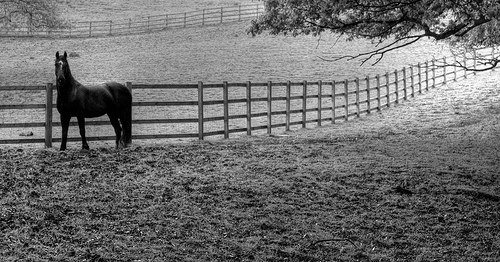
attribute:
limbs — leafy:
[235, 1, 499, 80]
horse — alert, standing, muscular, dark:
[48, 39, 141, 155]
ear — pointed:
[51, 47, 62, 63]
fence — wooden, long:
[1, 0, 271, 42]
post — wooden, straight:
[41, 80, 57, 159]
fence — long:
[0, 36, 499, 160]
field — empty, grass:
[2, 16, 500, 85]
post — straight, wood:
[192, 75, 208, 146]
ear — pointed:
[60, 44, 71, 61]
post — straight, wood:
[217, 74, 235, 146]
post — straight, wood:
[242, 75, 258, 143]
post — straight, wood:
[263, 74, 277, 142]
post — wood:
[281, 72, 297, 136]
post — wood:
[298, 74, 310, 135]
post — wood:
[315, 75, 326, 130]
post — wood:
[328, 74, 339, 129]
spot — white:
[57, 57, 65, 73]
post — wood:
[343, 75, 351, 129]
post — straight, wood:
[353, 70, 363, 123]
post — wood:
[364, 71, 374, 119]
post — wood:
[384, 69, 394, 113]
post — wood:
[374, 70, 385, 118]